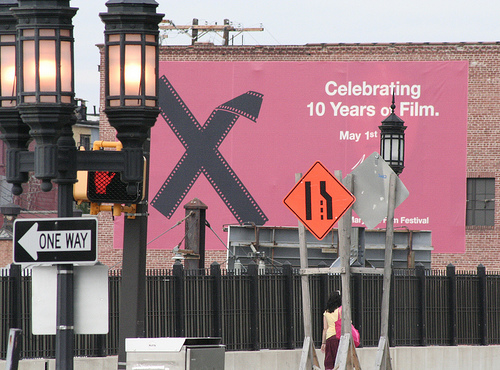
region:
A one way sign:
[13, 220, 100, 261]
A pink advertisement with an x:
[159, 68, 462, 252]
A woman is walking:
[324, 290, 344, 367]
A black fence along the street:
[412, 270, 499, 342]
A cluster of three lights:
[0, 3, 152, 136]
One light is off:
[380, 101, 408, 180]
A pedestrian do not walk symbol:
[96, 155, 145, 210]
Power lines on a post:
[163, 21, 274, 43]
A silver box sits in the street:
[128, 339, 222, 369]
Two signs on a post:
[16, 218, 112, 335]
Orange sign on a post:
[277, 148, 374, 267]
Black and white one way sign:
[7, 210, 97, 276]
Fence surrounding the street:
[159, 259, 303, 346]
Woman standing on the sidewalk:
[298, 277, 358, 367]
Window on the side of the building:
[468, 160, 498, 237]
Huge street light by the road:
[3, 8, 173, 197]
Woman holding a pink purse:
[331, 312, 373, 347]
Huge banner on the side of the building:
[160, 60, 490, 288]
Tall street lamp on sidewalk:
[371, 82, 418, 263]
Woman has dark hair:
[285, 290, 362, 335]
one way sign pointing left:
[11, 215, 99, 265]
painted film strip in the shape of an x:
[149, 74, 268, 224]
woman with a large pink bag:
[320, 288, 366, 369]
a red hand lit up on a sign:
[85, 168, 122, 200]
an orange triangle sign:
[281, 161, 357, 239]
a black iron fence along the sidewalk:
[2, 254, 497, 363]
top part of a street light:
[379, 89, 411, 181]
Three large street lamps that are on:
[1, 0, 160, 208]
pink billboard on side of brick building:
[113, 61, 468, 257]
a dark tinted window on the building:
[462, 170, 498, 225]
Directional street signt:
[14, 220, 99, 261]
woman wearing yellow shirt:
[325, 309, 339, 339]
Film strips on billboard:
[163, 60, 272, 229]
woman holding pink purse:
[323, 305, 344, 337]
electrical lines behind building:
[168, 17, 280, 44]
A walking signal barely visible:
[86, 161, 138, 203]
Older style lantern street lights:
[1, 2, 137, 190]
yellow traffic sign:
[281, 164, 352, 239]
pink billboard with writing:
[275, 65, 472, 150]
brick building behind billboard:
[170, 47, 492, 62]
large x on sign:
[161, 79, 256, 234]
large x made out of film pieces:
[157, 69, 275, 285]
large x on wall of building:
[158, 66, 290, 269]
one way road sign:
[6, 208, 118, 289]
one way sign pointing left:
[26, 219, 126, 276]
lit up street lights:
[98, 14, 193, 140]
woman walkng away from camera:
[316, 282, 366, 360]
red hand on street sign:
[95, 152, 130, 210]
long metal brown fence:
[186, 266, 316, 344]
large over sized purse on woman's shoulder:
[335, 311, 373, 356]